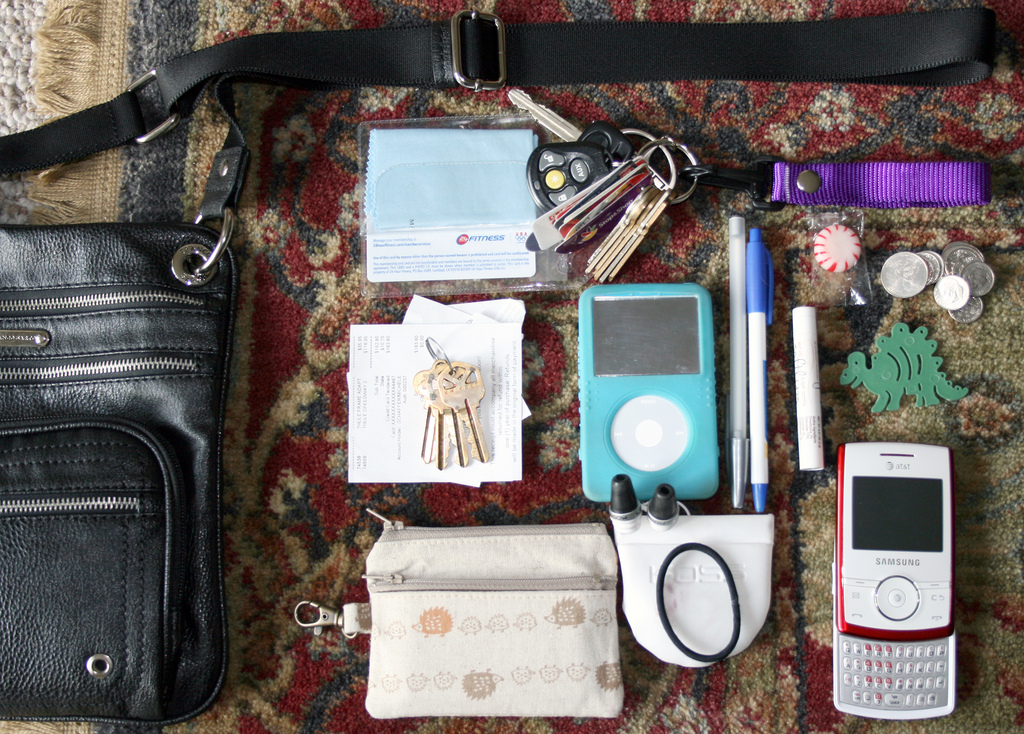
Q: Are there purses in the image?
A: Yes, there is a purse.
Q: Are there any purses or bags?
A: Yes, there is a purse.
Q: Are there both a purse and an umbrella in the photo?
A: No, there is a purse but no umbrellas.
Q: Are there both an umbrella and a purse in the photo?
A: No, there is a purse but no umbrellas.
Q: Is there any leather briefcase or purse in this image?
A: Yes, there is a leather purse.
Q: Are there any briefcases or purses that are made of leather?
A: Yes, the purse is made of leather.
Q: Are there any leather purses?
A: Yes, there is a purse that is made of leather.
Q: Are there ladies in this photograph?
A: No, there are no ladies.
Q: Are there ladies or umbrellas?
A: No, there are no ladies or umbrellas.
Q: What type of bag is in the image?
A: The bag is a purse.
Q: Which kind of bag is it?
A: The bag is a purse.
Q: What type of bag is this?
A: This is a purse.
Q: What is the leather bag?
A: The bag is a purse.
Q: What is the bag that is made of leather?
A: The bag is a purse.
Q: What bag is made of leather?
A: The bag is a purse.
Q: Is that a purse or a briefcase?
A: That is a purse.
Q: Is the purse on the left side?
A: Yes, the purse is on the left of the image.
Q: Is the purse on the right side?
A: No, the purse is on the left of the image.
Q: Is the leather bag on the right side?
A: No, the purse is on the left of the image.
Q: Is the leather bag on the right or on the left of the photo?
A: The purse is on the left of the image.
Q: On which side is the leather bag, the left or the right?
A: The purse is on the left of the image.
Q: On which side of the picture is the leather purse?
A: The purse is on the left of the image.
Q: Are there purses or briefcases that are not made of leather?
A: No, there is a purse but it is made of leather.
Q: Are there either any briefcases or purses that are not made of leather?
A: No, there is a purse but it is made of leather.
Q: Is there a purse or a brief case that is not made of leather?
A: No, there is a purse but it is made of leather.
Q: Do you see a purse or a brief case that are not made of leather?
A: No, there is a purse but it is made of leather.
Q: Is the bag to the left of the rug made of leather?
A: Yes, the purse is made of leather.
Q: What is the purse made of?
A: The purse is made of leather.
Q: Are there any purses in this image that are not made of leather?
A: No, there is a purse but it is made of leather.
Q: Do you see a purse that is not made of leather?
A: No, there is a purse but it is made of leather.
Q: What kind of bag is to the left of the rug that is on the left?
A: The bag is a purse.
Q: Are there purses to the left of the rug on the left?
A: Yes, there is a purse to the left of the rug.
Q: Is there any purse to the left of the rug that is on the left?
A: Yes, there is a purse to the left of the rug.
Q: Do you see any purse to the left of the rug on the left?
A: Yes, there is a purse to the left of the rug.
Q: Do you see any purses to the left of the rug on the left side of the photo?
A: Yes, there is a purse to the left of the rug.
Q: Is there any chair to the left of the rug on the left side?
A: No, there is a purse to the left of the rug.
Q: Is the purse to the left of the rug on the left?
A: Yes, the purse is to the left of the rug.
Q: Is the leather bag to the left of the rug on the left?
A: Yes, the purse is to the left of the rug.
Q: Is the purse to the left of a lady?
A: No, the purse is to the left of the rug.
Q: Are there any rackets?
A: No, there are no rackets.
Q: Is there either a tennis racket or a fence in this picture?
A: No, there are no rackets or fences.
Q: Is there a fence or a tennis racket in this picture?
A: No, there are no rackets or fences.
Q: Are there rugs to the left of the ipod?
A: Yes, there is a rug to the left of the ipod.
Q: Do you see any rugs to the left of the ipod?
A: Yes, there is a rug to the left of the ipod.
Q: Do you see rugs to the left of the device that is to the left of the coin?
A: Yes, there is a rug to the left of the ipod.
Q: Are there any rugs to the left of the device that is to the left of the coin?
A: Yes, there is a rug to the left of the ipod.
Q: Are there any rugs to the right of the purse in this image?
A: Yes, there is a rug to the right of the purse.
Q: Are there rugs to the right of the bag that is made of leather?
A: Yes, there is a rug to the right of the purse.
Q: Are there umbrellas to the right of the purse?
A: No, there is a rug to the right of the purse.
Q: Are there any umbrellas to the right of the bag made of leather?
A: No, there is a rug to the right of the purse.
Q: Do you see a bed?
A: No, there are no beds.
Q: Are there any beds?
A: No, there are no beds.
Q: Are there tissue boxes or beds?
A: No, there are no beds or tissue boxes.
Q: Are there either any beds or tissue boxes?
A: No, there are no beds or tissue boxes.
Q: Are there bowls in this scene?
A: No, there are no bowls.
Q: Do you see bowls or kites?
A: No, there are no bowls or kites.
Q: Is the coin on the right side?
A: Yes, the coin is on the right of the image.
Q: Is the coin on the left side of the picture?
A: No, the coin is on the right of the image.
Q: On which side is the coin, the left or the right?
A: The coin is on the right of the image.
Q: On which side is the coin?
A: The coin is on the right of the image.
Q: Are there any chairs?
A: No, there are no chairs.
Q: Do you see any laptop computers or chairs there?
A: No, there are no chairs or laptop computers.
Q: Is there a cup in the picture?
A: No, there are no cups.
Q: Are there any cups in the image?
A: No, there are no cups.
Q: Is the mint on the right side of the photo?
A: Yes, the mint is on the right of the image.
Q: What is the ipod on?
A: The ipod is on the rug.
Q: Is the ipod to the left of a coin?
A: Yes, the ipod is to the left of a coin.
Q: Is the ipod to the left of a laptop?
A: No, the ipod is to the left of a coin.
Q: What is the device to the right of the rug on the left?
A: The device is an ipod.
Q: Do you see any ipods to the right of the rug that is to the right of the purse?
A: Yes, there is an ipod to the right of the rug.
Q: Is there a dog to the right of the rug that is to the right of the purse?
A: No, there is an ipod to the right of the rug.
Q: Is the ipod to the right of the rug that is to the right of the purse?
A: Yes, the ipod is to the right of the rug.